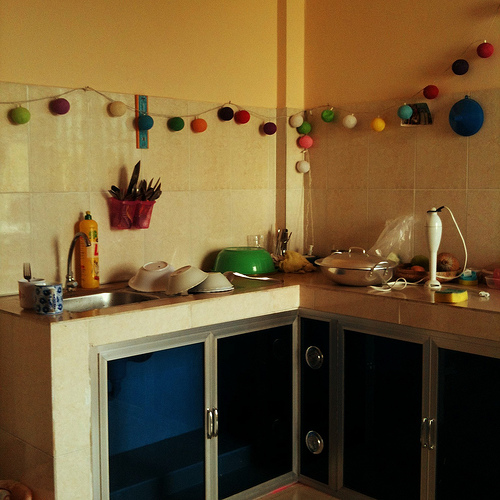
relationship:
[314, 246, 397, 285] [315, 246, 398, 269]
pot and lid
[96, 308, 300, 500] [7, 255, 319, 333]
cabinet under counter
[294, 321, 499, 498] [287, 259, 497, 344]
cabinets under counter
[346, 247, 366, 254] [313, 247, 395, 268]
handle on lid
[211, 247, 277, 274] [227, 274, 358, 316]
green item on counter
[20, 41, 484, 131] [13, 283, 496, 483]
items above counter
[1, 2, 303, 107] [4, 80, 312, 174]
wall above item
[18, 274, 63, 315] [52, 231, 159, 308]
mugs by sink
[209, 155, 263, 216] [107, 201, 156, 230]
wall mounted basket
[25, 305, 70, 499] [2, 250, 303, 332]
corner of counter